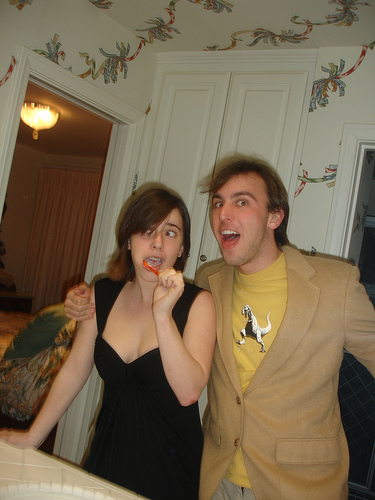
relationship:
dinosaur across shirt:
[234, 303, 272, 351] [226, 255, 288, 385]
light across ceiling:
[21, 98, 61, 141] [25, 84, 115, 162]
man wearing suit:
[189, 154, 372, 495] [188, 250, 371, 497]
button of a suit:
[233, 436, 244, 447] [188, 250, 371, 497]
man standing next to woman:
[189, 154, 372, 495] [0, 180, 216, 498]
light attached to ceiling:
[21, 98, 61, 141] [16, 81, 112, 156]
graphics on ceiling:
[136, 0, 231, 44] [88, 0, 373, 50]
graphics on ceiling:
[204, 0, 364, 51] [88, 0, 373, 50]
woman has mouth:
[0, 180, 216, 498] [141, 255, 165, 269]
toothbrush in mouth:
[140, 258, 158, 279] [141, 255, 165, 269]